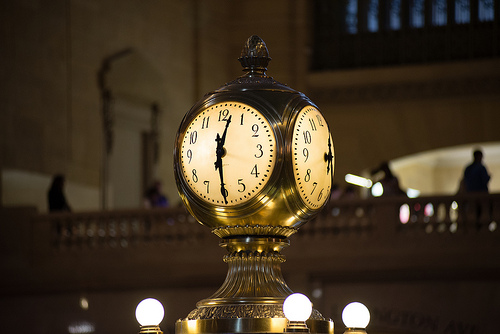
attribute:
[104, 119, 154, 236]
door — white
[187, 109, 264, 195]
numbers — black font, few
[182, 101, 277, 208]
clock — golden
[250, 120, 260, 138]
number — 2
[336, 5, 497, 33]
windows — high up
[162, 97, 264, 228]
clock — ornate, multi faced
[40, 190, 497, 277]
barrier — decorative, stone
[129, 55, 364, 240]
clock — round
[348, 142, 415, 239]
bulb — large, round, light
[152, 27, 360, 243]
piece — decorative